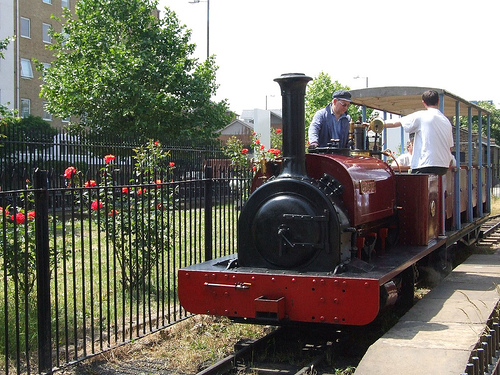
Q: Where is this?
A: This is at the amusement park.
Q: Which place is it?
A: It is an amusement park.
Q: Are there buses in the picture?
A: No, there are no buses.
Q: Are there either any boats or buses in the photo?
A: No, there are no buses or boats.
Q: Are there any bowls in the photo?
A: No, there are no bowls.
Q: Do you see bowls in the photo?
A: No, there are no bowls.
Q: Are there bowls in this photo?
A: No, there are no bowls.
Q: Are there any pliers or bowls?
A: No, there are no bowls or pliers.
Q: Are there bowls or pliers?
A: No, there are no bowls or pliers.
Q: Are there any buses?
A: No, there are no buses.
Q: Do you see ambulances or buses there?
A: No, there are no buses or ambulances.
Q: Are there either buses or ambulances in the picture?
A: No, there are no buses or ambulances.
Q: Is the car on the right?
A: Yes, the car is on the right of the image.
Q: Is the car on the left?
A: No, the car is on the right of the image.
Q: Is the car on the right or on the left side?
A: The car is on the right of the image.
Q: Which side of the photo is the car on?
A: The car is on the right of the image.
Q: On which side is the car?
A: The car is on the right of the image.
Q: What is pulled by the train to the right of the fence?
A: The car is pulled by the train.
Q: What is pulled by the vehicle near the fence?
A: The car is pulled by the train.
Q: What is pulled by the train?
A: The car is pulled by the train.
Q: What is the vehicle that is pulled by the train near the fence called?
A: The vehicle is a car.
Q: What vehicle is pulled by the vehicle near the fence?
A: The vehicle is a car.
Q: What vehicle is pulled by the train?
A: The vehicle is a car.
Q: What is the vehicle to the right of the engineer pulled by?
A: The car is pulled by the train.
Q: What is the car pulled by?
A: The car is pulled by the train.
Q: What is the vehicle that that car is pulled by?
A: The vehicle is a train.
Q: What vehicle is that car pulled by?
A: The car is pulled by the train.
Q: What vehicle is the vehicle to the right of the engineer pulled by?
A: The car is pulled by the train.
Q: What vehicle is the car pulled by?
A: The car is pulled by the train.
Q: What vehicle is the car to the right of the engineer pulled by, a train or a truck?
A: The car is pulled by a train.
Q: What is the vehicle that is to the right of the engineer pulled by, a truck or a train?
A: The car is pulled by a train.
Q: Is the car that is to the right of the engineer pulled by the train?
A: Yes, the car is pulled by the train.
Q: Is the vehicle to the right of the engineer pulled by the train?
A: Yes, the car is pulled by the train.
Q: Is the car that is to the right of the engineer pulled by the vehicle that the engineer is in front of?
A: Yes, the car is pulled by the train.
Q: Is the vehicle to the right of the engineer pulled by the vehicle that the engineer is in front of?
A: Yes, the car is pulled by the train.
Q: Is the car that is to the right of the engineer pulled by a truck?
A: No, the car is pulled by the train.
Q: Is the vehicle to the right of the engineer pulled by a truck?
A: No, the car is pulled by the train.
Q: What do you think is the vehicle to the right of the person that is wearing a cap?
A: The vehicle is a car.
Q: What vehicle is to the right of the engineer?
A: The vehicle is a car.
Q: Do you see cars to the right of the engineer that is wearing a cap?
A: Yes, there is a car to the right of the engineer.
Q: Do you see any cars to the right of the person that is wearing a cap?
A: Yes, there is a car to the right of the engineer.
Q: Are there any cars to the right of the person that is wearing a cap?
A: Yes, there is a car to the right of the engineer.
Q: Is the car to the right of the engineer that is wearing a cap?
A: Yes, the car is to the right of the engineer.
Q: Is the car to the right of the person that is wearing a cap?
A: Yes, the car is to the right of the engineer.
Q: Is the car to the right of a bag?
A: No, the car is to the right of the engineer.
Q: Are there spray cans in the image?
A: No, there are no spray cans.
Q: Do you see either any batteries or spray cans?
A: No, there are no spray cans or batteries.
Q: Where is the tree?
A: The tree is in the amusement park.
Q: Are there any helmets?
A: No, there are no helmets.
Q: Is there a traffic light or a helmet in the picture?
A: No, there are no helmets or traffic lights.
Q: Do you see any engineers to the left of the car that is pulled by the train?
A: Yes, there is an engineer to the left of the car.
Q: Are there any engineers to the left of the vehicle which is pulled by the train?
A: Yes, there is an engineer to the left of the car.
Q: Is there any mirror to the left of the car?
A: No, there is an engineer to the left of the car.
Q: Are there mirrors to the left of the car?
A: No, there is an engineer to the left of the car.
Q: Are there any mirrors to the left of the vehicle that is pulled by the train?
A: No, there is an engineer to the left of the car.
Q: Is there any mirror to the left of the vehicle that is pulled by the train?
A: No, there is an engineer to the left of the car.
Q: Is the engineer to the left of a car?
A: Yes, the engineer is to the left of a car.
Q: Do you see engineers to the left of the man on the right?
A: Yes, there is an engineer to the left of the man.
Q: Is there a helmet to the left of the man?
A: No, there is an engineer to the left of the man.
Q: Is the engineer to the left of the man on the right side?
A: Yes, the engineer is to the left of the man.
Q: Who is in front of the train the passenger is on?
A: The engineer is in front of the train.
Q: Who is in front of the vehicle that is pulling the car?
A: The engineer is in front of the train.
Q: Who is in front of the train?
A: The engineer is in front of the train.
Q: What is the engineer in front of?
A: The engineer is in front of the train.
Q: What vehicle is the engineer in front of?
A: The engineer is in front of the train.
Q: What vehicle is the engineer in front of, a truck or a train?
A: The engineer is in front of a train.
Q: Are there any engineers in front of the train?
A: Yes, there is an engineer in front of the train.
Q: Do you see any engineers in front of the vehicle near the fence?
A: Yes, there is an engineer in front of the train.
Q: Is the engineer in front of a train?
A: Yes, the engineer is in front of a train.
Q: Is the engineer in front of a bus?
A: No, the engineer is in front of a train.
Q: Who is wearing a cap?
A: The engineer is wearing a cap.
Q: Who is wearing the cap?
A: The engineer is wearing a cap.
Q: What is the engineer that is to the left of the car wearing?
A: The engineer is wearing a cap.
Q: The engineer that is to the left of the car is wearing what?
A: The engineer is wearing a cap.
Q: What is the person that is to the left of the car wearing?
A: The engineer is wearing a cap.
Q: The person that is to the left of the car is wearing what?
A: The engineer is wearing a cap.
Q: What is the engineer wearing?
A: The engineer is wearing a cap.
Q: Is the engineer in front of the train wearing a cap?
A: Yes, the engineer is wearing a cap.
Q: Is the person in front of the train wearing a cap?
A: Yes, the engineer is wearing a cap.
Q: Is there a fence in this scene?
A: Yes, there is a fence.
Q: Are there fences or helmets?
A: Yes, there is a fence.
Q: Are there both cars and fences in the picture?
A: Yes, there are both a fence and a car.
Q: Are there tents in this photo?
A: No, there are no tents.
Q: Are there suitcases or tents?
A: No, there are no tents or suitcases.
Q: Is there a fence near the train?
A: Yes, there is a fence near the train.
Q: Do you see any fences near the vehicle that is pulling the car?
A: Yes, there is a fence near the train.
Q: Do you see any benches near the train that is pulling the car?
A: No, there is a fence near the train.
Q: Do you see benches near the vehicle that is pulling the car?
A: No, there is a fence near the train.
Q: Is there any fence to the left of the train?
A: Yes, there is a fence to the left of the train.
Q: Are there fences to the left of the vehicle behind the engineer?
A: Yes, there is a fence to the left of the train.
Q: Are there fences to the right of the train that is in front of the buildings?
A: No, the fence is to the left of the train.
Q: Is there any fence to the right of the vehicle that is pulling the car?
A: No, the fence is to the left of the train.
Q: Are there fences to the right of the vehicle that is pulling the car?
A: No, the fence is to the left of the train.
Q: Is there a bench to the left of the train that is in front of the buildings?
A: No, there is a fence to the left of the train.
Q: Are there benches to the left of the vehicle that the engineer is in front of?
A: No, there is a fence to the left of the train.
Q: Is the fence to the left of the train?
A: Yes, the fence is to the left of the train.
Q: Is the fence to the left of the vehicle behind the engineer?
A: Yes, the fence is to the left of the train.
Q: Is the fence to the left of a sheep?
A: No, the fence is to the left of the train.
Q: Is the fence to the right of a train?
A: No, the fence is to the left of a train.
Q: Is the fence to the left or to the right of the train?
A: The fence is to the left of the train.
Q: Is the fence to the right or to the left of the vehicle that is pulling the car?
A: The fence is to the left of the train.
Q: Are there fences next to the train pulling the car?
A: Yes, there is a fence next to the train.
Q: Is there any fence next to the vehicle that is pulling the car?
A: Yes, there is a fence next to the train.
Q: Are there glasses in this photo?
A: No, there are no glasses.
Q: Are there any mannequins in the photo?
A: No, there are no mannequins.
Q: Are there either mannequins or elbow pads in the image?
A: No, there are no mannequins or elbow pads.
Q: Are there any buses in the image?
A: No, there are no buses.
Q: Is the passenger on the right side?
A: Yes, the passenger is on the right of the image.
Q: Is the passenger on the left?
A: No, the passenger is on the right of the image.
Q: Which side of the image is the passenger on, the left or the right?
A: The passenger is on the right of the image.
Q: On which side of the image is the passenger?
A: The passenger is on the right of the image.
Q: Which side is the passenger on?
A: The passenger is on the right of the image.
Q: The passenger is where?
A: The passenger is on the train.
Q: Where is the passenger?
A: The passenger is on the train.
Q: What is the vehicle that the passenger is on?
A: The vehicle is a train.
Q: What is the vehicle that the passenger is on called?
A: The vehicle is a train.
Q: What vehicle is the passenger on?
A: The passenger is on the train.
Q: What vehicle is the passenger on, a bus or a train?
A: The passenger is on a train.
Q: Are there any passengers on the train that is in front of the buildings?
A: Yes, there is a passenger on the train.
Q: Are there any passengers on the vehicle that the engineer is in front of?
A: Yes, there is a passenger on the train.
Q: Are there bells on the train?
A: No, there is a passenger on the train.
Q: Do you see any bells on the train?
A: No, there is a passenger on the train.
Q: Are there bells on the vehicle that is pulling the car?
A: No, there is a passenger on the train.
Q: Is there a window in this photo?
A: Yes, there is a window.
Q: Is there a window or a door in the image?
A: Yes, there is a window.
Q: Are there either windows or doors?
A: Yes, there is a window.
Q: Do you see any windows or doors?
A: Yes, there is a window.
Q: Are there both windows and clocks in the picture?
A: No, there is a window but no clocks.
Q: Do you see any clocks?
A: No, there are no clocks.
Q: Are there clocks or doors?
A: No, there are no clocks or doors.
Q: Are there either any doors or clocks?
A: No, there are no clocks or doors.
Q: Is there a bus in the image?
A: No, there are no buses.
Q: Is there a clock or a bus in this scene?
A: No, there are no buses or clocks.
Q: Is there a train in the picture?
A: Yes, there is a train.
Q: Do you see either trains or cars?
A: Yes, there is a train.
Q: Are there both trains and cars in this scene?
A: Yes, there are both a train and cars.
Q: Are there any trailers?
A: No, there are no trailers.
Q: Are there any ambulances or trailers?
A: No, there are no trailers or ambulances.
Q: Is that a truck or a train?
A: That is a train.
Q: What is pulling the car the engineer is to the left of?
A: The train is pulling the car.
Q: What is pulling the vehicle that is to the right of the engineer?
A: The train is pulling the car.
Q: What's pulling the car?
A: The train is pulling the car.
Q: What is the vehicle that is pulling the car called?
A: The vehicle is a train.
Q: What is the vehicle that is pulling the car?
A: The vehicle is a train.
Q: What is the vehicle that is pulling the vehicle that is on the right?
A: The vehicle is a train.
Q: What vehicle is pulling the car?
A: The vehicle is a train.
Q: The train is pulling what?
A: The train is pulling the car.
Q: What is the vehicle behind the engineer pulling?
A: The train is pulling the car.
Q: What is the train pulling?
A: The train is pulling the car.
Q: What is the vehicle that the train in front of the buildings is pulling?
A: The vehicle is a car.